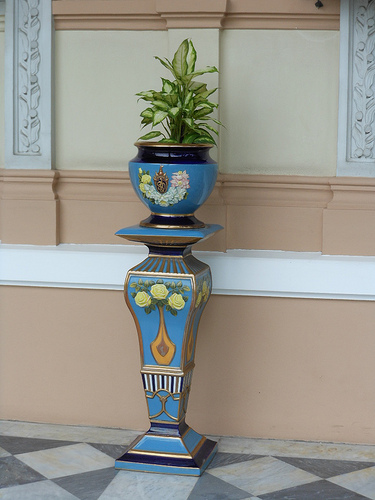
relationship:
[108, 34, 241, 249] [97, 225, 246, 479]
vase on top of stand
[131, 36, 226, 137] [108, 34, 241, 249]
plant inside vase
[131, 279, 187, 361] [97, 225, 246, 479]
flower across stand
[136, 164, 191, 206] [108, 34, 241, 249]
flower across vase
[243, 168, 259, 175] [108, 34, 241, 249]
molding beside vase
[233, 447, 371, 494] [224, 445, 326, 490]
floor has marble tile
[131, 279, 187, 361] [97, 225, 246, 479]
flowers across stand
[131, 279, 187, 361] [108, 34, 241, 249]
flower across vase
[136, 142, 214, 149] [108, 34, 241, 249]
crest on vase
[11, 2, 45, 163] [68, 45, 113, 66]
design across wall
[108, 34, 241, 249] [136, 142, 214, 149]
vase has gold lining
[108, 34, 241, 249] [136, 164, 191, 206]
vase has a design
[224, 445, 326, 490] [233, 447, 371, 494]
tile has checker pattern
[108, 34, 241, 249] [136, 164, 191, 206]
vase has design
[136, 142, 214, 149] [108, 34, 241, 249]
crest across vase